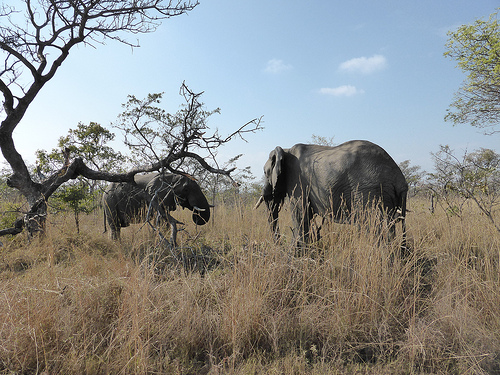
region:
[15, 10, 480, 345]
two wild animals face to face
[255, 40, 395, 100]
white clouds in the blue sky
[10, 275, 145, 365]
tall brown grass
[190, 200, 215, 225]
elephant's tusks and curled trunk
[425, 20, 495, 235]
thin green-leafed trees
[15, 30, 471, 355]
two elephants in their natural habitat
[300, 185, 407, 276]
tall grass in front of the body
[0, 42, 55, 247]
bare, dark branches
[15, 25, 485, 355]
wide, flat savanna and its inhabitants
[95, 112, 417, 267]
large elephant and a smaller one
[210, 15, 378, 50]
Bright blue sky above.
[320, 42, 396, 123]
Puffy white clouds in the sky.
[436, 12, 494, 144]
Tree with green leaves.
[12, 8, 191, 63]
Tree with no leaves.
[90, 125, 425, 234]
Two elephants facing each other.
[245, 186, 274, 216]
White tusk on the elephant.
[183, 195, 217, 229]
Smaller tusk on the little elephant.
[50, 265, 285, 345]
Very dry brush grass.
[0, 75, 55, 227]
The tree trunk is very crooked.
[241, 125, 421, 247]
Meet Duke the elephant.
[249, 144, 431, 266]
adult elephant in the wild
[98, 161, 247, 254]
baby elephant in the wild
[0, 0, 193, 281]
bare tree in wild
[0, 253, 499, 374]
grass that is brown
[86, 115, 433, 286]
elephants in the wild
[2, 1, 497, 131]
blue sky with clouds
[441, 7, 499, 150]
tree growing with leaves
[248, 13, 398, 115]
clouds in the blue sky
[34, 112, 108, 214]
small tree with green leaves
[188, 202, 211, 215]
tusks of the elephant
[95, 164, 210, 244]
elephant scratching his back on tree limb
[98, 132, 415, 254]
two elephants standing together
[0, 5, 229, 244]
tree trunk and branches with no leaves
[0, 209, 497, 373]
long dry grass elephants are standing in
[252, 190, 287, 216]
white tusks of larger elephant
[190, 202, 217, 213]
white tusks of smaller elephant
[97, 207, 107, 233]
tail of smaller gray elephant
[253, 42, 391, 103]
wispy clouds in the blue sky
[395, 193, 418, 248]
tail of larger gray elephant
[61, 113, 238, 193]
branch elephant is scratching his back on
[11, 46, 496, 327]
two elephants in the wild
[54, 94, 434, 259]
both elephants have tusks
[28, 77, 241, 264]
this elephant is under a tree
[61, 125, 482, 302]
the grass is long and yellow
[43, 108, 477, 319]
they are in africa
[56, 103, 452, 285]
the elephants are african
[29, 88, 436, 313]
two elephants in the Savannah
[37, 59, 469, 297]
the elephants face each other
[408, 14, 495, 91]
this tree has green leaves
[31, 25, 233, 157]
these trees are bare